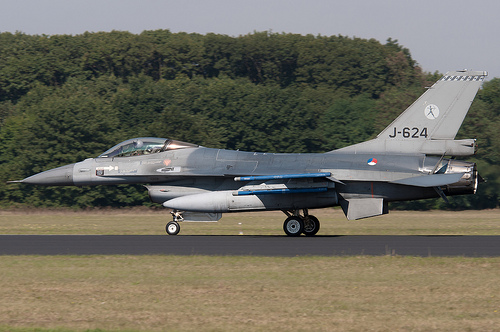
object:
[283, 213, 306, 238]
tire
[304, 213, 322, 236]
tire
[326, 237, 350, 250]
patch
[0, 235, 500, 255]
asphalt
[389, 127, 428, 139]
j-624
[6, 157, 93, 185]
front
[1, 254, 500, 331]
area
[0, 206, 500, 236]
area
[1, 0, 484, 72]
sky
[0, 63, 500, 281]
plane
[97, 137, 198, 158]
window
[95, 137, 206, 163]
cockpit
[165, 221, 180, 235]
gear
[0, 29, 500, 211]
trees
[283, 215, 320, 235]
wheels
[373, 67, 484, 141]
tail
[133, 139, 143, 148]
pilot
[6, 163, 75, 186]
nose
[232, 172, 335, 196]
wing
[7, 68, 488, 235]
airplane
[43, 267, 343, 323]
grass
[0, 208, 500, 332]
ground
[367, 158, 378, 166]
circle